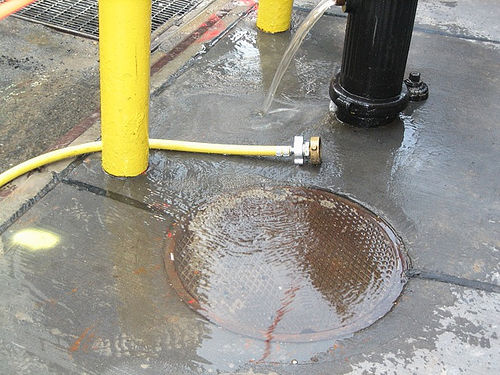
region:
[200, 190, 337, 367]
Man hole is brown in color.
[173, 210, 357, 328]
Man hole is covered in water.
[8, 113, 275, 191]
Yellow hose laying on ground.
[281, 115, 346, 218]
Metal connector piece on hose.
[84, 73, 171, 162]
Yellow pole sticking out of ground.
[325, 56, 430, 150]
Black fire hydrant on sidewalk.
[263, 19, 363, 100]
Water coming out of fire hydrant.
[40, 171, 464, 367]
Water is covering ground.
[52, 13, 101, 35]
Metal grate on ground.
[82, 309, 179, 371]
Footprint on the ground.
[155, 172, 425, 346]
manhole cover in a sidewalk covered in water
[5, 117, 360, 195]
yellow hose on a sidewalk leaking water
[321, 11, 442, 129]
black post on the sidewalk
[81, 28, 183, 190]
yellow parking post on curb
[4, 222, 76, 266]
sunlight spot on sidewalk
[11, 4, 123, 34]
street grate on the street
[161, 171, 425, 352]
water covered manhole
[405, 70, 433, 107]
black bolt used to secure post to the ground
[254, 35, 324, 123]
stream of water from the hydrant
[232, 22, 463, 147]
black fire hydrant pouring water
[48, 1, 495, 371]
a sidewalk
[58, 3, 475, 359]
a sidewalk flooded with water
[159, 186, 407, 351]
a manhole on the sidewalk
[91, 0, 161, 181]
a yellow post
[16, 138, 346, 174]
a yellow hose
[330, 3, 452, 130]
a black fire hydrant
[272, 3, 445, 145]
the fire hydrant is open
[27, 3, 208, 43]
a metal drain in the road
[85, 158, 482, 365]
water is on the pavement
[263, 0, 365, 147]
water is pouring out of the hydrant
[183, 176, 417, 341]
A sewer on the floor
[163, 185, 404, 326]
Wet sewer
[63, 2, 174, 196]
Yellow pole here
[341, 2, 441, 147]
A pole for a traffic light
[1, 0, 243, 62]
A gutter by the walkway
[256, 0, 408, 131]
Water falling on to the floor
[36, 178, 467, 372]
Cement pavement here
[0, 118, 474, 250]
A water hose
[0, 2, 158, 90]
Orange wiring near the corner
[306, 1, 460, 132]
The pole is black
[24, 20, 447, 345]
Picture taken outside.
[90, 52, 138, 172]
A metal pole.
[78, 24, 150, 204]
The pole is yellow.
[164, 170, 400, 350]
The street cover is round.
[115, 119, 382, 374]
The sidewalk is wet.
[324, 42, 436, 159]
A fire hydrant.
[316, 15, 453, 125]
The fire hydrant is black.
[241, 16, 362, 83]
Water is flowing out of the fire hydrant.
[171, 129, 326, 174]
A hose is on the ground.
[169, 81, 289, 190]
The hose is yellow.